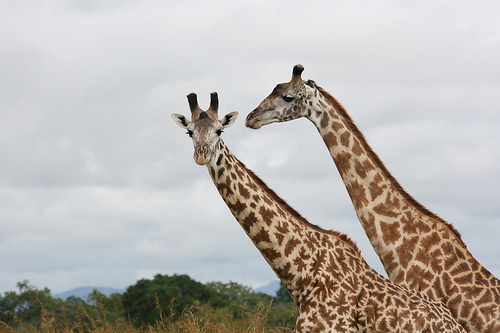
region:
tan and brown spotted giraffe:
[161, 81, 233, 316]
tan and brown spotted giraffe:
[242, 62, 464, 303]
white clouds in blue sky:
[37, 36, 96, 100]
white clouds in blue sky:
[19, 103, 85, 175]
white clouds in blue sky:
[113, 130, 155, 194]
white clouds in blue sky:
[9, 168, 55, 225]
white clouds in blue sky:
[98, 204, 133, 245]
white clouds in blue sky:
[140, 199, 186, 250]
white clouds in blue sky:
[132, 30, 183, 76]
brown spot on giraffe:
[371, 202, 401, 219]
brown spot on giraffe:
[378, 217, 403, 244]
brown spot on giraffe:
[395, 233, 420, 267]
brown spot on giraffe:
[406, 263, 434, 292]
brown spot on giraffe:
[428, 248, 445, 275]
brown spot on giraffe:
[226, 198, 248, 215]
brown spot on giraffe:
[241, 211, 260, 231]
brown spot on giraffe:
[248, 225, 273, 246]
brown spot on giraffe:
[272, 217, 290, 235]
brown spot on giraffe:
[284, 235, 302, 257]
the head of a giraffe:
[160, 35, 305, 172]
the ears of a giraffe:
[144, 105, 258, 151]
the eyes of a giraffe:
[157, 123, 234, 141]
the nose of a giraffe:
[186, 143, 232, 175]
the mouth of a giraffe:
[238, 105, 280, 182]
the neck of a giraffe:
[300, 80, 455, 253]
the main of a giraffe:
[311, 64, 468, 246]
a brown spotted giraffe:
[315, 126, 459, 295]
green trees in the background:
[100, 231, 247, 306]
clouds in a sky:
[76, 128, 176, 258]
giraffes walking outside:
[107, 46, 454, 326]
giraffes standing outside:
[152, 46, 484, 325]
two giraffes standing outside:
[123, 46, 419, 323]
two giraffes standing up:
[139, 57, 476, 267]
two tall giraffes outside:
[140, 83, 497, 312]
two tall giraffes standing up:
[155, 61, 460, 331]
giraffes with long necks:
[152, 68, 487, 318]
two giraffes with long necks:
[142, 56, 497, 326]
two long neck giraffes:
[130, 57, 499, 312]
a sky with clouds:
[34, 27, 499, 319]